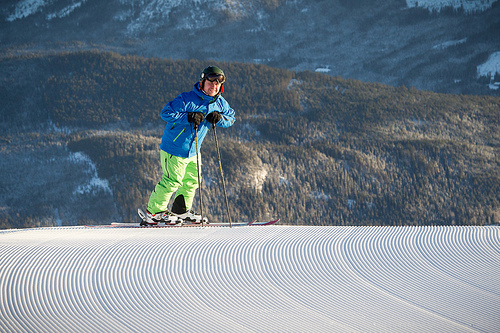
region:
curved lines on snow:
[127, 233, 302, 298]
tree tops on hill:
[343, 94, 410, 158]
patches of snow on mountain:
[137, 1, 224, 29]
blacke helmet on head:
[197, 65, 227, 81]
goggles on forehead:
[204, 73, 230, 88]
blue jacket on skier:
[155, 84, 236, 157]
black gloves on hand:
[187, 107, 224, 131]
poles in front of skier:
[184, 120, 232, 220]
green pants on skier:
[146, 144, 210, 220]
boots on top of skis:
[140, 203, 210, 231]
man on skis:
[136, 65, 278, 227]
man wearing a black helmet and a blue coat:
[173, 67, 225, 209]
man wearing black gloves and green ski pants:
[187, 70, 227, 211]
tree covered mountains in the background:
[267, 79, 482, 211]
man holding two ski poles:
[188, 66, 237, 224]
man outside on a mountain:
[163, 61, 234, 224]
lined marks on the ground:
[27, 250, 482, 325]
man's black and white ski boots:
[147, 210, 205, 224]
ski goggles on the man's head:
[204, 72, 225, 82]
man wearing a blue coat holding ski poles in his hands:
[187, 64, 227, 211]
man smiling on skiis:
[97, 47, 285, 240]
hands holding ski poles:
[182, 95, 244, 230]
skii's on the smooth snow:
[102, 205, 287, 239]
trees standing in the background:
[20, 46, 484, 259]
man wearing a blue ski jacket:
[141, 77, 275, 157]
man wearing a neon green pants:
[147, 129, 240, 234]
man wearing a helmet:
[170, 47, 239, 97]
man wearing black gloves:
[176, 102, 243, 132]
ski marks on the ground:
[50, 217, 338, 307]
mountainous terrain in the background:
[11, 2, 441, 99]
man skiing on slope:
[102, 54, 284, 229]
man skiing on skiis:
[98, 55, 295, 237]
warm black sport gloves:
[188, 102, 225, 127]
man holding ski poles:
[135, 50, 238, 229]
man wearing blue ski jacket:
[137, 59, 246, 248]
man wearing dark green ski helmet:
[141, 56, 248, 235]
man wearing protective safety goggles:
[142, 48, 240, 231]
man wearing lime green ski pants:
[122, 50, 248, 227]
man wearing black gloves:
[137, 51, 239, 227]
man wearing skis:
[135, 52, 245, 229]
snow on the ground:
[333, 259, 450, 331]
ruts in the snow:
[222, 253, 319, 307]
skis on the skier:
[69, 202, 284, 233]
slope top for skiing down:
[200, 197, 444, 303]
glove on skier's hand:
[207, 106, 231, 129]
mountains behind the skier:
[386, 18, 476, 95]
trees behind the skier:
[347, 157, 426, 231]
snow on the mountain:
[458, 49, 492, 87]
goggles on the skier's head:
[193, 71, 232, 83]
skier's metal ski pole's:
[182, 116, 230, 241]